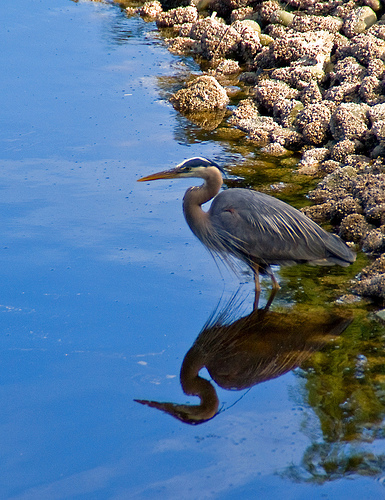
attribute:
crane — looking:
[115, 125, 369, 327]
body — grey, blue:
[209, 189, 356, 265]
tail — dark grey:
[311, 233, 356, 267]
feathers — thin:
[201, 221, 261, 290]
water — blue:
[22, 275, 79, 385]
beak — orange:
[127, 161, 180, 189]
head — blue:
[162, 152, 220, 184]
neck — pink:
[190, 169, 229, 204]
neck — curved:
[182, 170, 218, 223]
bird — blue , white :
[132, 141, 362, 324]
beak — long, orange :
[134, 166, 182, 191]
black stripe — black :
[183, 157, 220, 168]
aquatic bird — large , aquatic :
[136, 151, 367, 325]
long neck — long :
[176, 164, 217, 233]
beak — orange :
[129, 156, 180, 186]